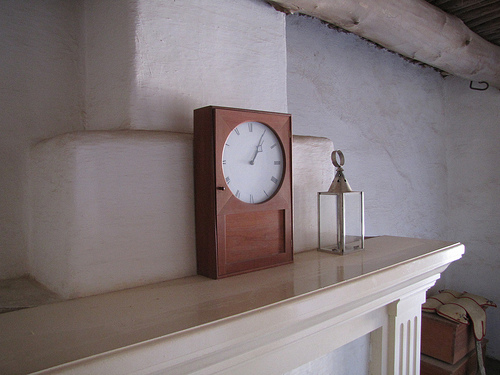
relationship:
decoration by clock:
[308, 144, 371, 254] [171, 97, 312, 272]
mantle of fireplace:
[1, 227, 468, 372] [5, 236, 470, 372]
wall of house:
[1, 2, 448, 372] [0, 2, 495, 372]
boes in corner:
[422, 289, 497, 341] [423, 255, 479, 353]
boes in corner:
[435, 287, 497, 304] [423, 255, 479, 353]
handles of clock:
[244, 126, 266, 168] [192, 105, 294, 280]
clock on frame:
[194, 104, 294, 277] [193, 104, 295, 278]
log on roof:
[266, 0, 498, 85] [423, 0, 498, 45]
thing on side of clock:
[324, 144, 392, 266] [195, 103, 305, 289]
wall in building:
[1, 2, 500, 363] [36, 28, 476, 311]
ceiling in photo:
[454, 9, 494, 34] [17, 29, 495, 357]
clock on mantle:
[192, 105, 294, 280] [1, 227, 468, 372]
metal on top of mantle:
[309, 146, 377, 268] [144, 270, 453, 332]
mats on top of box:
[433, 286, 483, 319] [419, 286, 487, 373]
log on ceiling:
[266, 0, 498, 85] [446, 4, 496, 18]